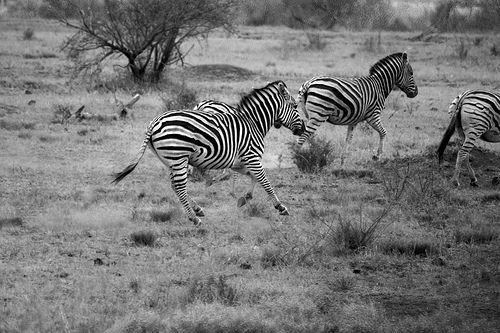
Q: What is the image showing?
A: It is showing a field.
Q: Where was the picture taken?
A: It was taken at the field.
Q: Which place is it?
A: It is a field.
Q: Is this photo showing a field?
A: Yes, it is showing a field.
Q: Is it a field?
A: Yes, it is a field.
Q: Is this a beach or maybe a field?
A: It is a field.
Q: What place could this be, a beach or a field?
A: It is a field.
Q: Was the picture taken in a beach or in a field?
A: It was taken at a field.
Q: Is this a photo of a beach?
A: No, the picture is showing a field.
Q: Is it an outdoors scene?
A: Yes, it is outdoors.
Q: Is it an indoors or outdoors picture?
A: It is outdoors.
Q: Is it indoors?
A: No, it is outdoors.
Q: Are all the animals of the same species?
A: Yes, all the animals are zebras.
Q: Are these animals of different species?
A: No, all the animals are zebras.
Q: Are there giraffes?
A: No, there are no giraffes.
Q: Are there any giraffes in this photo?
A: No, there are no giraffes.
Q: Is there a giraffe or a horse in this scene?
A: No, there are no giraffes or horses.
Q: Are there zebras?
A: Yes, there is a zebra.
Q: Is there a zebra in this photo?
A: Yes, there is a zebra.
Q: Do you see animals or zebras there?
A: Yes, there is a zebra.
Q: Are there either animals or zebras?
A: Yes, there is a zebra.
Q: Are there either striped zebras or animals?
A: Yes, there is a striped zebra.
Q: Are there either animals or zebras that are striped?
A: Yes, the zebra is striped.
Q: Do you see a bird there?
A: No, there are no birds.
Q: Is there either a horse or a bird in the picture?
A: No, there are no birds or horses.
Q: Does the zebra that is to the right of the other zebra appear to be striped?
A: Yes, the zebra is striped.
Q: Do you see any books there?
A: No, there are no books.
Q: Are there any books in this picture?
A: No, there are no books.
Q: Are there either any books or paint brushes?
A: No, there are no books or paint brushes.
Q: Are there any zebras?
A: Yes, there is a zebra.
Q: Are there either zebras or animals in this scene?
A: Yes, there is a zebra.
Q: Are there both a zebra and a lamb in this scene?
A: No, there is a zebra but no lambs.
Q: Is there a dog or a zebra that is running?
A: Yes, the zebra is running.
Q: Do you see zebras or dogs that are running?
A: Yes, the zebra is running.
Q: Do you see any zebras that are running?
A: Yes, there is a zebra that is running.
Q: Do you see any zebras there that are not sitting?
A: Yes, there is a zebra that is running .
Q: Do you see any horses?
A: No, there are no horses.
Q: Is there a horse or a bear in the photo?
A: No, there are no horses or bears.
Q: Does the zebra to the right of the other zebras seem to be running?
A: Yes, the zebra is running.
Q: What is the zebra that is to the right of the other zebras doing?
A: The zebra is running.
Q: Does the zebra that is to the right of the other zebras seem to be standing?
A: No, the zebra is running.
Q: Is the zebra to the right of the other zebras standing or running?
A: The zebra is running.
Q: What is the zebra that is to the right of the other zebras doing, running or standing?
A: The zebra is running.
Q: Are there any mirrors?
A: No, there are no mirrors.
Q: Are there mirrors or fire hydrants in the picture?
A: No, there are no mirrors or fire hydrants.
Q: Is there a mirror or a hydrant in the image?
A: No, there are no mirrors or fire hydrants.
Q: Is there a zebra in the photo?
A: Yes, there are zebras.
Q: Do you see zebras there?
A: Yes, there are zebras.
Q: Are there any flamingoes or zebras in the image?
A: Yes, there are zebras.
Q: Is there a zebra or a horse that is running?
A: Yes, the zebras are running.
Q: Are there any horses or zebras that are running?
A: Yes, the zebras are running.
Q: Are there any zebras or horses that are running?
A: Yes, the zebras are running.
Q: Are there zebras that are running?
A: Yes, there are zebras that are running.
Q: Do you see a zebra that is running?
A: Yes, there are zebras that are running.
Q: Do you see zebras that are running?
A: Yes, there are zebras that are running.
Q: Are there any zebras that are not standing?
A: Yes, there are zebras that are running.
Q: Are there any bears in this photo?
A: No, there are no bears.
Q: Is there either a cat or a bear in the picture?
A: No, there are no bears or cats.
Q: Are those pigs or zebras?
A: Those are zebras.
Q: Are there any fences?
A: No, there are no fences.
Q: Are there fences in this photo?
A: No, there are no fences.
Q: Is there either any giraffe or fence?
A: No, there are no fences or giraffes.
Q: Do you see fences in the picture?
A: No, there are no fences.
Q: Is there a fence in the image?
A: No, there are no fences.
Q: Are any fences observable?
A: No, there are no fences.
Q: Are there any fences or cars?
A: No, there are no fences or cars.